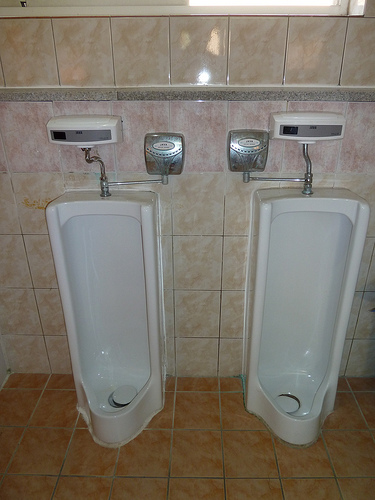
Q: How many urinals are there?
A: 2.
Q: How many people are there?
A: 0.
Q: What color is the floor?
A: Brown.